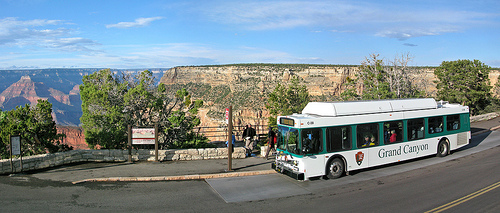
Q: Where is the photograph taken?
A: Grand Canyon.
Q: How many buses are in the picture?
A: One.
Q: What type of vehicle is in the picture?
A: Bus.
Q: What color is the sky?
A: Blue.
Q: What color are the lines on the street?
A: Yellow.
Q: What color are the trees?
A: Green.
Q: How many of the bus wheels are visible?
A: Two.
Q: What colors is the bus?
A: White and green.